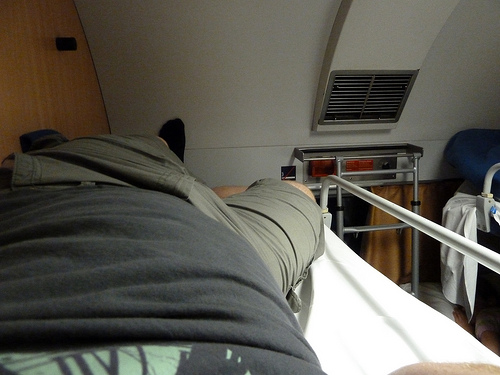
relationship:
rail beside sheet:
[303, 166, 499, 333] [232, 202, 495, 372]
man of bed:
[1, 115, 350, 374] [0, 175, 500, 374]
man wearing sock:
[1, 115, 350, 374] [157, 117, 187, 164]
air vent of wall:
[317, 61, 411, 127] [80, 5, 489, 185]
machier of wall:
[288, 137, 410, 192] [80, 5, 489, 185]